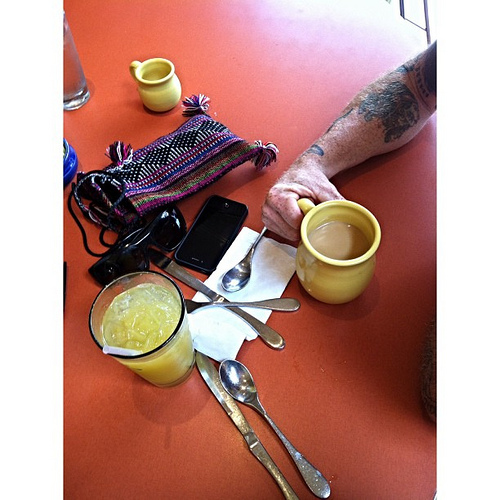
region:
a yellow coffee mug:
[295, 196, 382, 296]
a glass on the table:
[91, 275, 203, 390]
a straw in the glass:
[100, 340, 137, 355]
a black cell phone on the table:
[171, 190, 252, 265]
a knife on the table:
[190, 346, 290, 491]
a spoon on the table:
[221, 351, 336, 496]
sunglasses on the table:
[90, 205, 180, 270]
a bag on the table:
[81, 105, 266, 206]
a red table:
[76, 35, 426, 491]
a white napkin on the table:
[181, 227, 309, 353]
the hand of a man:
[254, 94, 379, 278]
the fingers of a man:
[261, 165, 373, 233]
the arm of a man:
[264, 88, 422, 251]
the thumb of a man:
[296, 140, 403, 223]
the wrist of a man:
[285, 109, 382, 189]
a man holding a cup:
[222, 131, 374, 295]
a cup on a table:
[256, 160, 441, 320]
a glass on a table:
[108, 271, 215, 403]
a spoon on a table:
[196, 301, 353, 446]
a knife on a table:
[178, 342, 235, 470]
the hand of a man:
[246, 158, 363, 279]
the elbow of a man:
[386, 20, 442, 155]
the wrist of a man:
[277, 128, 357, 184]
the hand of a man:
[254, 158, 375, 253]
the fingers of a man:
[235, 180, 343, 258]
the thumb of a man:
[296, 170, 360, 215]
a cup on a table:
[287, 183, 394, 310]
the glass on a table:
[108, 254, 236, 404]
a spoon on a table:
[222, 321, 287, 434]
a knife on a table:
[188, 344, 258, 458]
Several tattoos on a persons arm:
[254, 51, 442, 238]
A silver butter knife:
[194, 348, 311, 497]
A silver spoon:
[221, 351, 326, 485]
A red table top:
[63, 4, 433, 496]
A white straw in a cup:
[107, 341, 147, 368]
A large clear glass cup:
[82, 277, 209, 396]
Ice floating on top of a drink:
[104, 290, 173, 347]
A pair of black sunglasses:
[85, 197, 187, 283]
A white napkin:
[179, 217, 307, 369]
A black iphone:
[168, 186, 253, 286]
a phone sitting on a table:
[191, 192, 237, 267]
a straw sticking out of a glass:
[71, 277, 183, 382]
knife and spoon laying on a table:
[187, 350, 294, 463]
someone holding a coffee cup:
[265, 174, 387, 276]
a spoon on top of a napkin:
[200, 267, 280, 303]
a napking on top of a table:
[228, 242, 268, 270]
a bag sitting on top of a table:
[96, 147, 264, 184]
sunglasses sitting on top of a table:
[74, 205, 165, 272]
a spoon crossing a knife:
[166, 263, 257, 341]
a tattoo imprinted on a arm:
[347, 69, 410, 139]